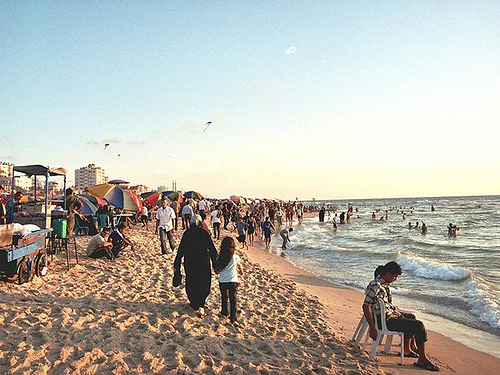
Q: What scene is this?
A: Beach scene.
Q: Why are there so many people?
A: It's a hot day.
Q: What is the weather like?
A: Sunny.